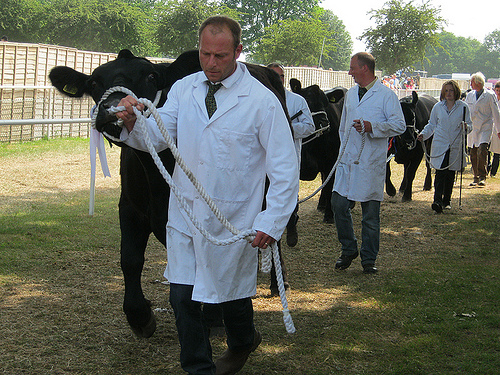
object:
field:
[0, 136, 499, 375]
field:
[112, 15, 299, 374]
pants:
[329, 191, 380, 267]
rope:
[130, 97, 239, 240]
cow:
[46, 48, 289, 336]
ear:
[47, 66, 92, 99]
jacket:
[119, 61, 298, 304]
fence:
[0, 42, 492, 145]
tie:
[203, 81, 225, 120]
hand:
[113, 94, 145, 135]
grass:
[0, 186, 125, 273]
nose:
[95, 99, 126, 138]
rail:
[1, 118, 87, 126]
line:
[116, 16, 472, 374]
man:
[114, 16, 299, 374]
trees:
[99, 0, 154, 58]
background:
[0, 0, 328, 87]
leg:
[117, 200, 157, 339]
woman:
[416, 80, 471, 216]